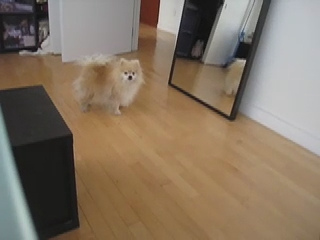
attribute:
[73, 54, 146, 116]
pomeranian — tan, small, fluffy, yellow, brown, looking, forward, beige, white, standing, fuzzy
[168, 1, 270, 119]
mirror — standing, leaning, black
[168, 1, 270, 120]
frame — brown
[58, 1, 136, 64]
door — white, open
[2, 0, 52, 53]
shelf — black, small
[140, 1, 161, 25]
door — dark, closed, brown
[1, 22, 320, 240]
flooring — hard, wood, brown, light, blonde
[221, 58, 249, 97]
reflection — reflected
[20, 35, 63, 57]
cloth — white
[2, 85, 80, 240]
box — large, black, square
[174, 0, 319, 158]
wall — white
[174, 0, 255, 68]
closet — reflected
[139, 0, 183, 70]
doorway — open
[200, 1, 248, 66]
door — white